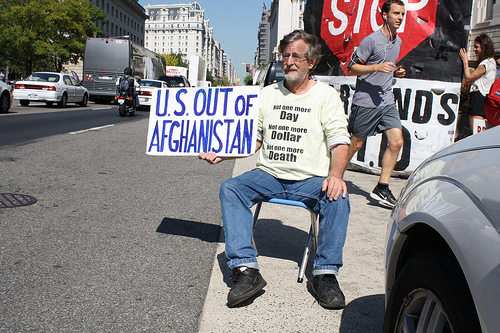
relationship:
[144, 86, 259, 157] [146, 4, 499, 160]
sign for protest